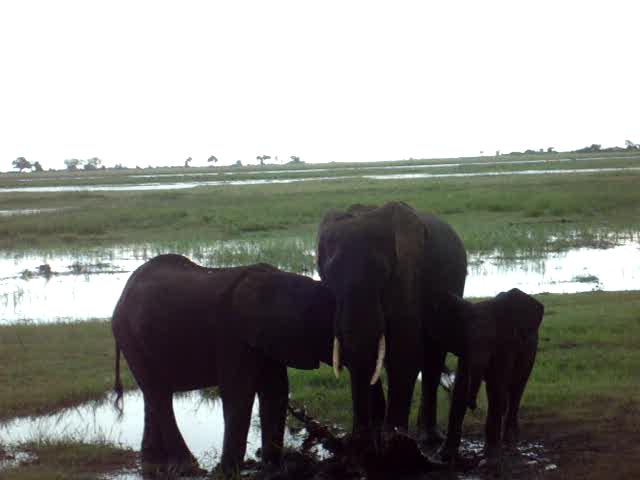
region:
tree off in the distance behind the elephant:
[9, 152, 29, 170]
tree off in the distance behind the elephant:
[30, 157, 43, 172]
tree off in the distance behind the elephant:
[64, 152, 77, 172]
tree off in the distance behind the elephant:
[81, 155, 99, 167]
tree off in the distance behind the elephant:
[180, 153, 192, 164]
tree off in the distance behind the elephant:
[205, 148, 217, 167]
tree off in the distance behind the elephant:
[252, 149, 265, 163]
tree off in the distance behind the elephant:
[266, 151, 276, 167]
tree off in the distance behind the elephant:
[288, 152, 298, 167]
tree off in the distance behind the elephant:
[544, 142, 555, 154]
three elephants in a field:
[87, 182, 558, 476]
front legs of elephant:
[207, 370, 305, 472]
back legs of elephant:
[134, 392, 203, 478]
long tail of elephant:
[103, 306, 134, 427]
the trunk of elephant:
[337, 313, 390, 474]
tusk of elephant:
[366, 330, 390, 388]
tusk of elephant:
[328, 328, 347, 384]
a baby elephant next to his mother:
[405, 222, 551, 468]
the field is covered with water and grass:
[3, 146, 634, 478]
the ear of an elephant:
[382, 209, 448, 318]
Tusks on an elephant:
[329, 335, 393, 381]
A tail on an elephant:
[117, 345, 125, 415]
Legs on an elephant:
[139, 372, 289, 478]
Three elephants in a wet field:
[106, 198, 546, 464]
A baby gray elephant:
[458, 289, 546, 460]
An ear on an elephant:
[391, 203, 430, 306]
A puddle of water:
[6, 372, 327, 473]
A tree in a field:
[10, 154, 32, 173]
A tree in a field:
[256, 153, 273, 169]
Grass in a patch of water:
[493, 220, 608, 269]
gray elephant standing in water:
[95, 228, 340, 478]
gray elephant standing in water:
[453, 275, 545, 470]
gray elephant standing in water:
[321, 190, 467, 452]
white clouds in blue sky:
[196, 50, 243, 92]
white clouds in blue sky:
[352, 59, 406, 121]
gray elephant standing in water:
[310, 189, 438, 380]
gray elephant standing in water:
[457, 277, 548, 479]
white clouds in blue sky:
[25, 25, 66, 58]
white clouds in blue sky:
[198, 12, 251, 47]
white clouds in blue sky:
[379, 21, 456, 85]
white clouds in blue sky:
[94, 18, 175, 72]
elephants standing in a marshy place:
[110, 202, 541, 458]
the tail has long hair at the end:
[110, 330, 123, 424]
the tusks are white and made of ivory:
[328, 329, 387, 387]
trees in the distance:
[7, 148, 311, 174]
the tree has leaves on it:
[9, 157, 28, 173]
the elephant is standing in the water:
[96, 241, 333, 478]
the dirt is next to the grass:
[537, 354, 636, 442]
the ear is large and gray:
[386, 203, 429, 288]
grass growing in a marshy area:
[3, 160, 634, 472]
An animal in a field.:
[90, 242, 347, 435]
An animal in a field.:
[333, 170, 461, 425]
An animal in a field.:
[422, 290, 545, 431]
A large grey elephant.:
[424, 288, 543, 454]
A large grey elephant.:
[313, 178, 441, 464]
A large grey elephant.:
[103, 275, 298, 421]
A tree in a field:
[178, 151, 194, 168]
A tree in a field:
[206, 155, 219, 165]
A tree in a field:
[254, 149, 275, 165]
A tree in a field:
[226, 156, 247, 169]